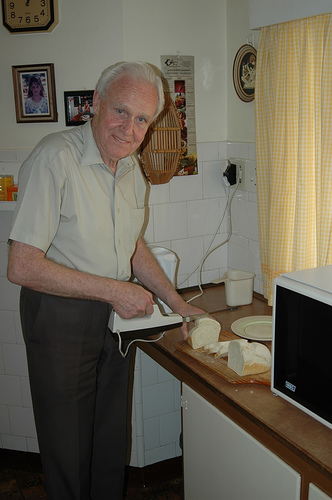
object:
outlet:
[248, 163, 258, 192]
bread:
[227, 334, 272, 373]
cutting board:
[174, 323, 270, 385]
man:
[11, 54, 200, 494]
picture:
[11, 60, 59, 123]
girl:
[26, 76, 46, 101]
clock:
[1, 3, 61, 34]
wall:
[98, 11, 180, 44]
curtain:
[256, 9, 327, 306]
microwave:
[271, 271, 330, 423]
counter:
[149, 273, 323, 419]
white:
[193, 207, 205, 233]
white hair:
[99, 65, 165, 86]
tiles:
[184, 196, 230, 239]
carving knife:
[108, 293, 208, 334]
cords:
[202, 203, 240, 237]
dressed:
[9, 117, 148, 489]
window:
[243, 14, 329, 281]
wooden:
[125, 88, 185, 189]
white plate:
[233, 306, 273, 349]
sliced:
[191, 313, 220, 352]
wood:
[206, 360, 225, 378]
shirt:
[10, 132, 163, 290]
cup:
[209, 269, 256, 307]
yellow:
[267, 51, 294, 79]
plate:
[232, 41, 258, 103]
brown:
[18, 281, 131, 498]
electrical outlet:
[226, 158, 239, 182]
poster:
[156, 54, 198, 173]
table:
[126, 274, 332, 497]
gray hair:
[96, 64, 165, 122]